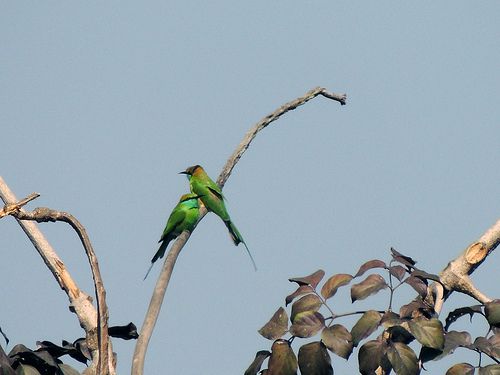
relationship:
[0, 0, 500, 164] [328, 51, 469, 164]
clouds in sky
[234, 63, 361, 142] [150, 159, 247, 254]
branch has birds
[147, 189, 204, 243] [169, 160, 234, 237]
bird sitting next to bird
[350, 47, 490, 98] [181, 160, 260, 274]
sky behind bird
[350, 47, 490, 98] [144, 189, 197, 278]
sky behind bird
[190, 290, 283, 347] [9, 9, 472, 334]
clouds in sky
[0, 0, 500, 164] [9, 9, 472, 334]
clouds in sky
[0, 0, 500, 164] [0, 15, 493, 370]
clouds in sky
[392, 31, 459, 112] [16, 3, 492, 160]
clouds in sky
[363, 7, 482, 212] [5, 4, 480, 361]
sky in photo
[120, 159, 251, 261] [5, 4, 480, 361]
birds in photo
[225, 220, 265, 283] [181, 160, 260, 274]
feather of bird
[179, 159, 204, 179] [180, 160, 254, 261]
head of bird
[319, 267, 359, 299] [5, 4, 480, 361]
leaf in photo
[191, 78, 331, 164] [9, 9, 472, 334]
clouds in sky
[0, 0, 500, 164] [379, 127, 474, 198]
clouds in sky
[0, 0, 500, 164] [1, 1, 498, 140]
clouds in sky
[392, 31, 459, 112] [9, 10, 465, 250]
clouds in sky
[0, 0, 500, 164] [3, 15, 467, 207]
clouds in sky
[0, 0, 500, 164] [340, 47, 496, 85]
clouds in sky